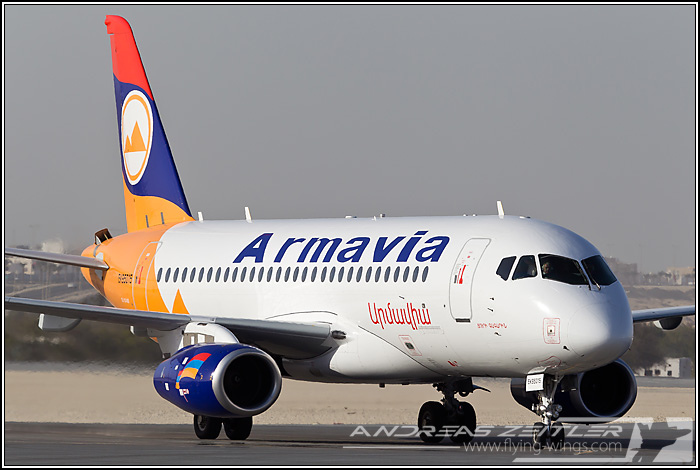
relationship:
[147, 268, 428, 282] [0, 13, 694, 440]
windows on airplane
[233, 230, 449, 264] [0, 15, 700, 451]
letter on plane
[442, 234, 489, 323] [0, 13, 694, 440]
door on airplane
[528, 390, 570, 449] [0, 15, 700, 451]
landing gear on plane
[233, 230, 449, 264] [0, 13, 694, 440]
letter on airplane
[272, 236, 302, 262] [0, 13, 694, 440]
letter on airplane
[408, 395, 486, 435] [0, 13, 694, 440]
gear on airplane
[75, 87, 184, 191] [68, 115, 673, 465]
logo on plane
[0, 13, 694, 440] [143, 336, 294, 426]
airplane has engine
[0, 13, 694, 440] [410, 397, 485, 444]
airplane has tire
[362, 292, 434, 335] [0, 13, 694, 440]
writing on airplane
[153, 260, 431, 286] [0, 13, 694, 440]
windows on airplane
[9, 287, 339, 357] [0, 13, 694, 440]
wing on airplane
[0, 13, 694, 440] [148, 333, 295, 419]
airplane has engine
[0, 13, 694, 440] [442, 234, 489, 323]
airplane has door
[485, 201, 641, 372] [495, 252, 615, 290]
cockpit has windshield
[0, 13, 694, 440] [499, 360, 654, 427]
airplane has engine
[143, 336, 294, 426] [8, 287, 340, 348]
engine on wing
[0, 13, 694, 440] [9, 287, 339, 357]
airplane has wing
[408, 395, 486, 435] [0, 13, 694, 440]
gear under airplane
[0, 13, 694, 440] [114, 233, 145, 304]
airplane has door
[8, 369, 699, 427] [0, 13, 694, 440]
dirt field behind airplane